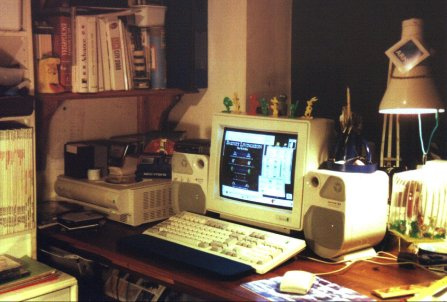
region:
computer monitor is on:
[206, 111, 336, 235]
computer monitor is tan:
[203, 113, 335, 239]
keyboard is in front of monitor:
[143, 207, 305, 274]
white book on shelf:
[76, 16, 88, 91]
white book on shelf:
[86, 14, 100, 90]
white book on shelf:
[96, 17, 105, 89]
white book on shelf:
[104, 15, 126, 89]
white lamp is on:
[378, 18, 443, 111]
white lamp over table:
[379, 17, 445, 116]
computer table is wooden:
[41, 218, 445, 300]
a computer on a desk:
[174, 66, 370, 222]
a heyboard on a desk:
[145, 204, 297, 264]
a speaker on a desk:
[290, 153, 422, 263]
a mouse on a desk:
[273, 255, 357, 295]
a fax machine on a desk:
[71, 155, 166, 229]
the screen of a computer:
[185, 117, 315, 212]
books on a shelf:
[43, 18, 180, 109]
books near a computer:
[38, 39, 300, 251]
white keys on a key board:
[158, 214, 218, 254]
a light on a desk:
[362, 32, 444, 123]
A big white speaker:
[302, 168, 389, 260]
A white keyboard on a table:
[140, 210, 305, 272]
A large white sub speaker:
[170, 152, 207, 213]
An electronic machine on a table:
[55, 168, 173, 224]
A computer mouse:
[280, 269, 313, 294]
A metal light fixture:
[378, 18, 442, 166]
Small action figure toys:
[220, 92, 316, 118]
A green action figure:
[219, 94, 232, 111]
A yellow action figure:
[230, 90, 242, 112]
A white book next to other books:
[73, 16, 89, 92]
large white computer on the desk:
[138, 104, 348, 278]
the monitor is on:
[203, 113, 306, 237]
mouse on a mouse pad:
[237, 263, 367, 300]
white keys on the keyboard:
[146, 208, 298, 277]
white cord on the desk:
[311, 249, 429, 273]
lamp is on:
[369, 20, 440, 170]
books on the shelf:
[34, 5, 177, 95]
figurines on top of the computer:
[214, 87, 322, 117]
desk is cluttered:
[43, 69, 444, 300]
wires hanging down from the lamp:
[412, 105, 444, 164]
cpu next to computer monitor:
[303, 167, 387, 260]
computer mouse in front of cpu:
[279, 269, 315, 293]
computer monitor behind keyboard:
[205, 110, 337, 236]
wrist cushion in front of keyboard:
[118, 231, 256, 282]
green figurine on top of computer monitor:
[222, 94, 233, 112]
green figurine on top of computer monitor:
[256, 96, 270, 114]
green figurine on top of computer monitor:
[288, 99, 303, 117]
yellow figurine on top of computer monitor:
[231, 90, 244, 114]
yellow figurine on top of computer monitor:
[271, 96, 280, 117]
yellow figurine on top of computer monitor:
[302, 94, 320, 117]